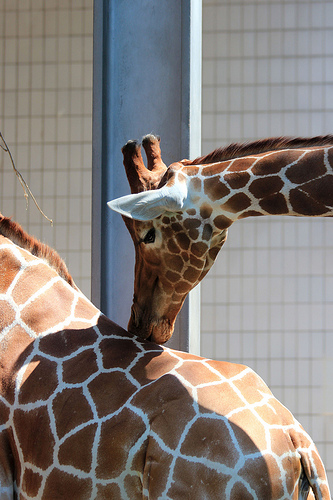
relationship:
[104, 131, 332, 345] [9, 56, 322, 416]
brown giraffe in front of building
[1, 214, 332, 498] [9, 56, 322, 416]
brown giraffe in front of building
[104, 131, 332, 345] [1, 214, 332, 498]
brown giraffe nibbling brown giraffe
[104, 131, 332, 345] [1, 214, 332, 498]
brown giraffe kissing brown giraffe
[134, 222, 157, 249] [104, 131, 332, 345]
eye of brown giraffe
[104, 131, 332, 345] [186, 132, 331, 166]
brown giraffe has hair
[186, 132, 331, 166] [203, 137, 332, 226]
hair on neck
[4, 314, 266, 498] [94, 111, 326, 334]
shade on giraffe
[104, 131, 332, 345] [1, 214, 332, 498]
brown giraffe sing brown giraffe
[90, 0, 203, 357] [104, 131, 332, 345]
beam behind brown giraffe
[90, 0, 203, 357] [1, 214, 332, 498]
beam behind brown giraffe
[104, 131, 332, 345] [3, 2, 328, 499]
brown giraffe photographed in zoo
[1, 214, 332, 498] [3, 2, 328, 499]
brown giraffe photographed in zoo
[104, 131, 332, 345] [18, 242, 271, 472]
brown giraffe licking other giraffe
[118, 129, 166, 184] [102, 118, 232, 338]
horns on a head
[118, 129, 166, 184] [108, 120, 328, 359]
horns on a giraffe.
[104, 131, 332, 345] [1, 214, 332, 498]
brown giraffe cleaning or brown giraffe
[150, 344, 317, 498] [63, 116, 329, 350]
rear of giraffe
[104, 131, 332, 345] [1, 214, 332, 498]
brown giraffe touching another brown giraffe